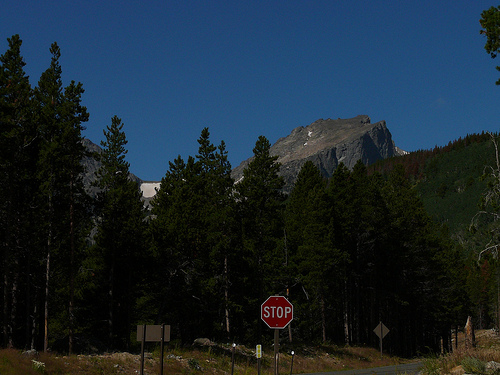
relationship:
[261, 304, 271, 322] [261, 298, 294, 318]
s in stop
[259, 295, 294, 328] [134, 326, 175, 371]
sign on poles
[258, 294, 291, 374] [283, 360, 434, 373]
sign on a road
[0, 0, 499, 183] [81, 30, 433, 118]
cloud in sky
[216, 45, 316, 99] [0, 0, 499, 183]
cloud in sky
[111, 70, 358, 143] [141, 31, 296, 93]
sky with clouds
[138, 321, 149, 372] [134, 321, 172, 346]
metal post behind a sign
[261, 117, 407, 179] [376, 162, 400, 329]
mountain sticking up above tree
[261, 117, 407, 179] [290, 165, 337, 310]
mountain sticking up above tree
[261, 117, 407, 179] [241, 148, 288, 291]
mountain sticking up above tree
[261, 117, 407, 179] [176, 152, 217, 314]
mountain sticking up above tree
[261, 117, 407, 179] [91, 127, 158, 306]
mountain sticking up above tree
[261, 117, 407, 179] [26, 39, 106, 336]
mountain sticking up above tree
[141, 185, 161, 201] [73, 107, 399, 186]
snow on mountain